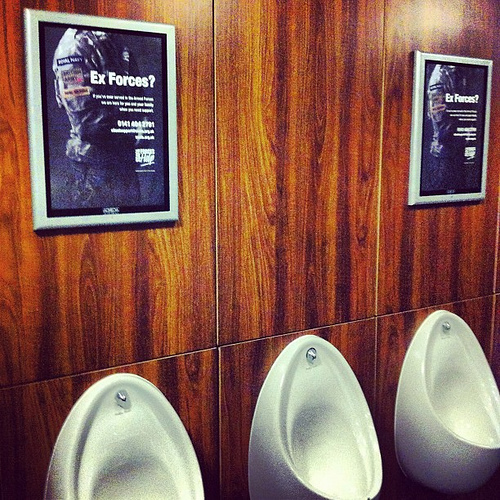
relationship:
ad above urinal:
[407, 48, 495, 206] [404, 299, 499, 463]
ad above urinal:
[407, 48, 495, 206] [264, 335, 380, 492]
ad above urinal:
[407, 48, 495, 206] [33, 367, 209, 486]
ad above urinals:
[407, 48, 495, 206] [40, 370, 205, 500]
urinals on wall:
[40, 370, 205, 500] [9, 0, 482, 420]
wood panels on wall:
[211, 0, 383, 348] [0, 6, 495, 499]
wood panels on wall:
[0, 345, 223, 500] [0, 6, 495, 499]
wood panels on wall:
[375, 0, 499, 317] [0, 6, 495, 499]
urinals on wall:
[47, 307, 497, 494] [242, 140, 373, 187]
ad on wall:
[407, 48, 495, 206] [0, 6, 495, 499]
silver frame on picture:
[408, 45, 495, 207] [418, 61, 485, 193]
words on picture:
[88, 68, 162, 125] [25, 15, 175, 219]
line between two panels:
[209, 0, 221, 350] [0, 0, 392, 395]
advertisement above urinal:
[20, 7, 185, 231] [51, 369, 209, 498]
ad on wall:
[19, 6, 179, 233] [11, 6, 484, 340]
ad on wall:
[407, 48, 495, 206] [11, 6, 484, 340]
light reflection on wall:
[386, 0, 476, 45] [0, 6, 495, 499]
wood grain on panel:
[304, 24, 340, 193] [232, 15, 381, 312]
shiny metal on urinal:
[440, 319, 452, 330] [393, 308, 499, 493]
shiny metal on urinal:
[307, 347, 317, 364] [247, 333, 383, 499]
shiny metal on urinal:
[113, 390, 130, 407] [51, 369, 209, 498]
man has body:
[47, 24, 148, 209] [47, 25, 148, 210]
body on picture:
[47, 25, 148, 210] [13, 2, 190, 240]